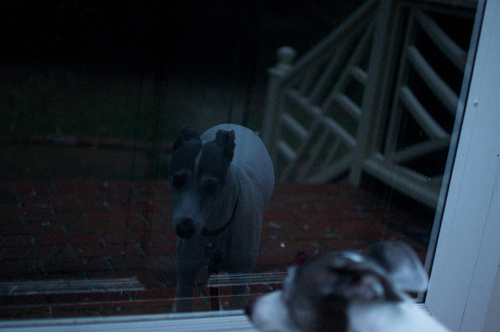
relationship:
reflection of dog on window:
[169, 124, 275, 318] [59, 88, 97, 182]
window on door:
[59, 88, 97, 182] [410, 161, 464, 235]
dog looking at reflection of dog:
[251, 245, 446, 329] [169, 124, 275, 318]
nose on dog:
[177, 219, 194, 234] [251, 245, 446, 329]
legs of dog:
[129, 257, 248, 303] [251, 245, 446, 329]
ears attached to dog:
[186, 128, 229, 163] [251, 245, 446, 329]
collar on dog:
[213, 219, 233, 235] [251, 245, 446, 329]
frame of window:
[440, 7, 478, 37] [59, 88, 97, 182]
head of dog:
[199, 134, 216, 146] [251, 245, 446, 329]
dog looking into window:
[251, 245, 446, 329] [59, 88, 97, 182]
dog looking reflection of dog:
[251, 245, 446, 329] [169, 124, 275, 318]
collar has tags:
[213, 219, 233, 235] [194, 238, 227, 251]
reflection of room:
[139, 10, 190, 42] [243, 5, 380, 81]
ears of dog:
[186, 128, 229, 163] [251, 245, 446, 329]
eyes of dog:
[172, 176, 218, 190] [251, 245, 446, 329]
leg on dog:
[142, 243, 209, 300] [251, 245, 446, 329]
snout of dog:
[176, 215, 195, 223] [251, 245, 446, 329]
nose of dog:
[177, 219, 194, 234] [251, 245, 446, 329]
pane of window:
[455, 17, 474, 34] [59, 88, 97, 182]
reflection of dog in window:
[169, 124, 275, 318] [59, 88, 97, 182]